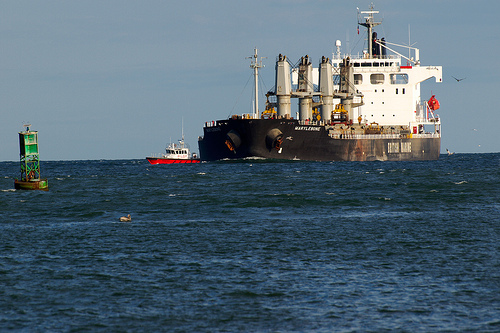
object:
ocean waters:
[92, 156, 249, 271]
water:
[0, 152, 146, 186]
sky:
[0, 0, 500, 153]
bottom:
[147, 159, 200, 164]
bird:
[452, 76, 466, 82]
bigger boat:
[197, 3, 441, 163]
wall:
[369, 108, 424, 137]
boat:
[146, 117, 202, 165]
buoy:
[14, 121, 49, 190]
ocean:
[0, 153, 499, 331]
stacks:
[336, 55, 360, 126]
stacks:
[316, 55, 336, 126]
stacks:
[297, 55, 313, 125]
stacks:
[273, 52, 294, 120]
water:
[83, 217, 233, 303]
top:
[161, 148, 189, 159]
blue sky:
[58, 42, 214, 113]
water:
[360, 163, 463, 263]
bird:
[121, 214, 132, 221]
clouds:
[109, 29, 238, 69]